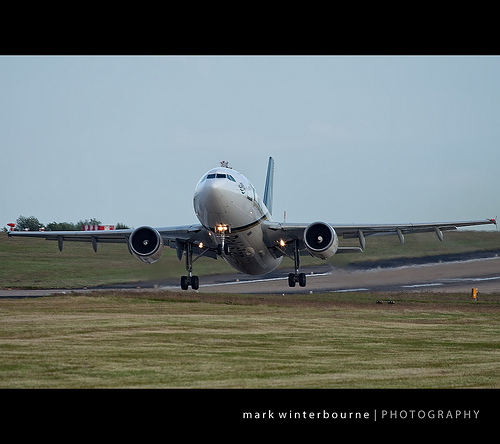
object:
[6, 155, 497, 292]
plane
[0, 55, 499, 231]
sky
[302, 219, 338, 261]
engine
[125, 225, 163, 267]
engine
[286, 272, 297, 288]
wheel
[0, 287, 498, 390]
grass